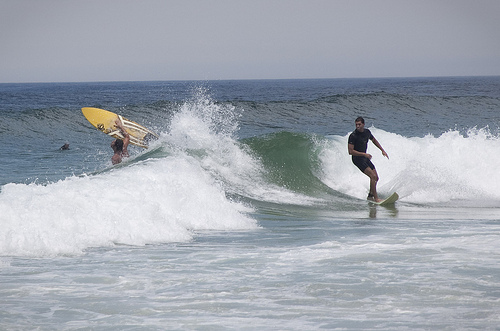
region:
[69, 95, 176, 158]
surfer falling from board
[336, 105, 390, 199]
surfer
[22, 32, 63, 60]
white clouds in blue sky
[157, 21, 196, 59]
white clouds in blue sky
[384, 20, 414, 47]
white clouds in blue sky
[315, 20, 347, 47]
white clouds in blue sky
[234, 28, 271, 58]
white clouds in blue sky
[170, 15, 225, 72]
white clouds in blue sky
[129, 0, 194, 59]
white clouds in blue sky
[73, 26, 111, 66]
white clouds in blue sky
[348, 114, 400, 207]
a man is surfing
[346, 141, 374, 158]
arm of a man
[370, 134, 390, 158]
arm of a man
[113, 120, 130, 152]
arm of a man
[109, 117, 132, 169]
a man is in the water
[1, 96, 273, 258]
a wave is crashing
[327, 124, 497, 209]
a wave is crashing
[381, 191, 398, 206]
tip of a surfboard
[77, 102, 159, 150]
a bright yellow surfboard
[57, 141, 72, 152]
a person is in water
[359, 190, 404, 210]
Man on a board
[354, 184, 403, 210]
Man is on a board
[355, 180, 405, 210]
Man on a surfboard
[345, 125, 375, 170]
Man wearing a wet suit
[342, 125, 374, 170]
Man is wearing a wet suit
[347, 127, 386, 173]
Man wearing a black wet suit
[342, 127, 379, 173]
Man is wearing a black wet suit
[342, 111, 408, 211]
Man riding a wave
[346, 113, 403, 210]
Man is riding a wave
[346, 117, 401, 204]
surfer riding a wave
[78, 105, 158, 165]
surfer holding a surfboard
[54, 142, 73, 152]
swinner in the ocean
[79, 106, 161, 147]
yellow surfboard with white stripes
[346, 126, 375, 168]
black wetsuit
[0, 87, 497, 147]
a wave in the ocean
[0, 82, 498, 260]
white water from crashing wave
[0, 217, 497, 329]
white foam on top of ocean water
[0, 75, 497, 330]
an ocean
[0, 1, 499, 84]
hazy blue sky above the ocean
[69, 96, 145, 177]
surfer falling off board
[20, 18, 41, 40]
white clouds in blue sky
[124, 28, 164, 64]
white clouds in blue sky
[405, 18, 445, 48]
white clouds in blue sky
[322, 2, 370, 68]
white clouds in blue sky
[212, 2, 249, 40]
white clouds in blue sky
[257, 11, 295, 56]
white clouds in blue sky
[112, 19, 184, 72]
white clouds in blue sky